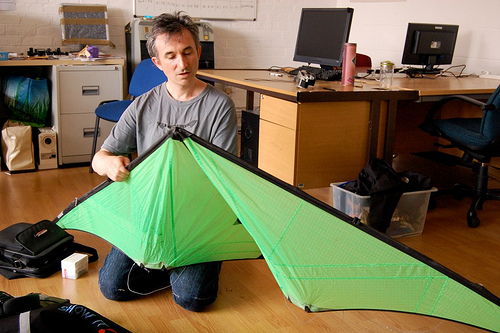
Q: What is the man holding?
A: Kite.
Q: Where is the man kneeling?
A: On floor.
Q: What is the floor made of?
A: Wood.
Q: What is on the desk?
A: Computer monitor.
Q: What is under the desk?
A: Chair.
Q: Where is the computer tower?
A: Under the desk.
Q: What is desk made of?
A: Wood.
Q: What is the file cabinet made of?
A: Metal.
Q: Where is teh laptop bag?
A: Floor.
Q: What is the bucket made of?
A: Plastic.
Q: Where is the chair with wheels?
A: Under the desk to the right of the man.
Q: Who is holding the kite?
A: The man in the picture.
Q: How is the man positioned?
A: On his knees.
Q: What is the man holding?
A: A green kite.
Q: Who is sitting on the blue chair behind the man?
A: Nobody is.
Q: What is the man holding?
A: A kite.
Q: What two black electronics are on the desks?
A: Computer monitors.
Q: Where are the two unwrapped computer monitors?
A: On the desks.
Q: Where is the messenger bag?
A: On the floor.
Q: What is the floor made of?
A: Wood.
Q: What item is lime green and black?
A: The kite.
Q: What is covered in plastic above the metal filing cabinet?
A: A computer monitor.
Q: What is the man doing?
A: Holding a kite.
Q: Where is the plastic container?
A: On the floor.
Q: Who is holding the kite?
A: The man.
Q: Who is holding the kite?
A: The man.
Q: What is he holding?
A: A stunt kite.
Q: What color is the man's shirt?
A: Gray.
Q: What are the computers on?
A: Desk.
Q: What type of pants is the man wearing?
A: Jeans.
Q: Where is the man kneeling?
A: Floor.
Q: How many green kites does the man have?
A: One.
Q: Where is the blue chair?
A: Behind the man.